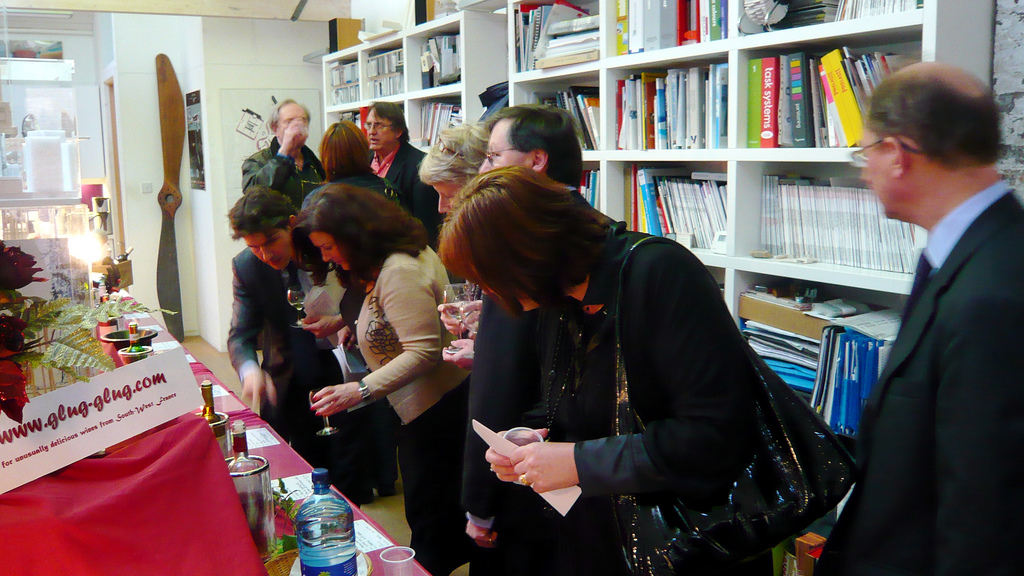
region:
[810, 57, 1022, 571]
man wearing a black suit jacket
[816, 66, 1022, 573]
man wearing eyeglasses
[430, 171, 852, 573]
woman carrying a black purse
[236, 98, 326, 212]
man drinking a beverage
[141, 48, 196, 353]
wooden propeller leaning on a wall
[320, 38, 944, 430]
bookshelf full of books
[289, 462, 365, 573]
a clear blue bottle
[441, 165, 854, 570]
woman holding a piece of paper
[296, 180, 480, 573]
woman holding a wine glass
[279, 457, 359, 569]
a bottle of water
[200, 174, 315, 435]
a man is pointing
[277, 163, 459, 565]
woman is looking to a table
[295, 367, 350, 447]
hand holding a glass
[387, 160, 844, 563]
woman hand holding a paper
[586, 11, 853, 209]
shelf is full of books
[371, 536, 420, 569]
the glass is plastic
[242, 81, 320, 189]
man drinking from a cup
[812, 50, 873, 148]
book is color yellow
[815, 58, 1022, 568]
Man in dark suit standing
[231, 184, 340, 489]
Man pointing at a paper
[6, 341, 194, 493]
White and red sign with a website address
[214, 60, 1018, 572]
People standing around a table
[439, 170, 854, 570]
Girl holding a paper and her bag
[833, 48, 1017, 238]
A man is wearing glasses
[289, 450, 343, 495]
The cap of a water bottle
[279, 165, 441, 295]
Woman has long brown hair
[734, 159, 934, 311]
A row of white books on a shelf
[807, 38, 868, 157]
Yellow binder of a book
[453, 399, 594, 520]
White paper in two hands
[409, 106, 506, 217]
Person has blonde hair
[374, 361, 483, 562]
A pair of black pants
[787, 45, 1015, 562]
A man wearing a suit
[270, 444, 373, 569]
A blue water bottle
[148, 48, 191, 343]
wood propeller on wall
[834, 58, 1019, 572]
Man with receding hairline wearing glasses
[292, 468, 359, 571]
Blue bottle of water on table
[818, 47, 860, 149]
yellow book on bookshelf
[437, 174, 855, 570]
red haired woman with black purse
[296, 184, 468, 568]
women holding wine glass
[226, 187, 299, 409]
man holding wine glass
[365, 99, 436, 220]
man wearing black jacket and pink shirt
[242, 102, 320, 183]
man drinking from a glass